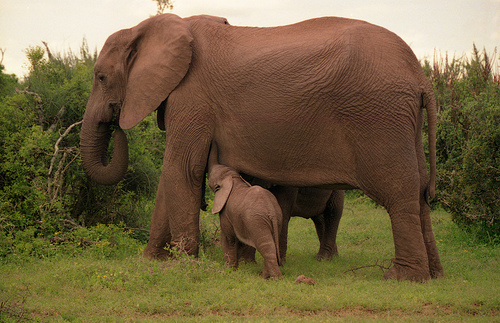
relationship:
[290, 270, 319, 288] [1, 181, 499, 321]
brown rock in grass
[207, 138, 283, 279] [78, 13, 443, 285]
baby elephant behind mother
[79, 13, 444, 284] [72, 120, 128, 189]
elephant has trunk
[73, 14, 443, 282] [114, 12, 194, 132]
elephant has ear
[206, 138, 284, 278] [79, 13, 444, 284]
baby elephant under elephant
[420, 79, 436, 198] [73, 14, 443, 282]
tail of elephant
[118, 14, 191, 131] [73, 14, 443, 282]
ear of elephant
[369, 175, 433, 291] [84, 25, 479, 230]
leg of elephant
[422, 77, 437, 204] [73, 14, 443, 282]
tail of elephant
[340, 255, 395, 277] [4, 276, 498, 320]
branch on ground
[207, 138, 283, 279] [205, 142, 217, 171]
baby elephant has trunk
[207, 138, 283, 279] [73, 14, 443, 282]
baby elephant nex to elephant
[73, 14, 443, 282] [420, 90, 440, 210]
elephant has tail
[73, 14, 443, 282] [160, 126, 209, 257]
elephant has front leg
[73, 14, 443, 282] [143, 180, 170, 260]
elephant has front leg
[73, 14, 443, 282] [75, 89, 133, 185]
elephant has trunk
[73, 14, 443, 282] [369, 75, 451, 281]
elephant has leg